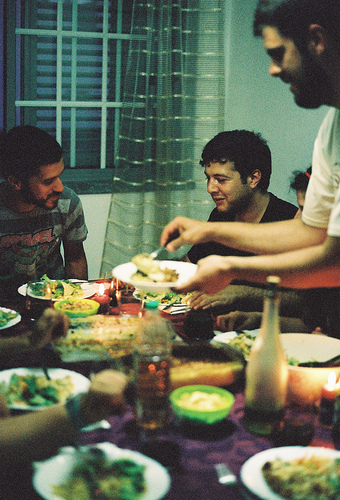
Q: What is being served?
A: Salad.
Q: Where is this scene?
A: Dinner table.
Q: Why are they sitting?
A: Eating.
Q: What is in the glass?
A: Beverage.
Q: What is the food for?
A: Eating.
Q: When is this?
A: Dinner time.